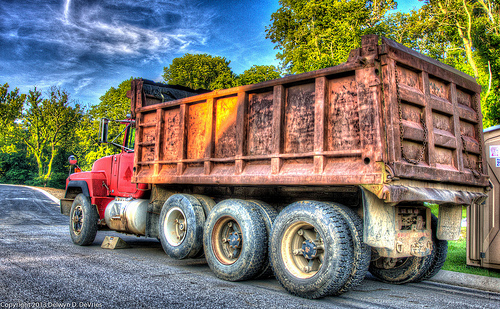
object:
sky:
[1, 1, 274, 96]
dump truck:
[60, 33, 490, 300]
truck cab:
[65, 121, 147, 218]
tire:
[68, 193, 97, 245]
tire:
[158, 193, 204, 260]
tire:
[268, 200, 353, 299]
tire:
[203, 197, 281, 283]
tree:
[17, 89, 82, 183]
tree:
[0, 83, 27, 174]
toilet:
[467, 124, 500, 272]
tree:
[165, 53, 232, 91]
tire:
[267, 200, 372, 300]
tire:
[358, 203, 451, 285]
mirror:
[99, 118, 110, 145]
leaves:
[251, 74, 260, 79]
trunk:
[44, 148, 62, 178]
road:
[1, 185, 499, 307]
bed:
[129, 33, 490, 205]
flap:
[361, 188, 401, 253]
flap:
[436, 204, 465, 243]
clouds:
[0, 0, 223, 74]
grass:
[441, 240, 467, 278]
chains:
[393, 60, 427, 164]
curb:
[0, 183, 499, 296]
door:
[119, 123, 138, 193]